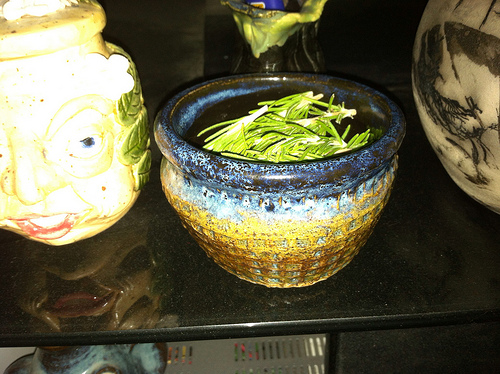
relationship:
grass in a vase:
[195, 90, 372, 163] [152, 70, 406, 288]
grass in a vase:
[190, 83, 376, 171] [152, 70, 406, 288]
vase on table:
[152, 70, 406, 288] [7, 2, 494, 353]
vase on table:
[152, 70, 408, 288] [77, 265, 220, 335]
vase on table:
[0, 2, 152, 249] [7, 2, 494, 353]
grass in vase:
[195, 90, 372, 163] [152, 70, 406, 288]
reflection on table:
[8, 197, 171, 338] [7, 2, 494, 353]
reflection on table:
[215, 277, 338, 307] [7, 2, 494, 353]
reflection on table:
[227, 24, 325, 78] [7, 2, 494, 353]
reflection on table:
[383, 110, 496, 313] [7, 2, 494, 353]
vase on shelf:
[152, 70, 406, 288] [0, 0, 499, 343]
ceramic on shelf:
[412, 0, 499, 214] [0, 0, 499, 343]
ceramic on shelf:
[0, 0, 153, 247] [0, 0, 499, 343]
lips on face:
[20, 204, 88, 246] [0, 72, 117, 248]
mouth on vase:
[15, 210, 75, 240] [152, 70, 406, 288]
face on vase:
[1, 41, 146, 244] [0, 2, 152, 249]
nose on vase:
[8, 126, 56, 206] [0, 2, 152, 249]